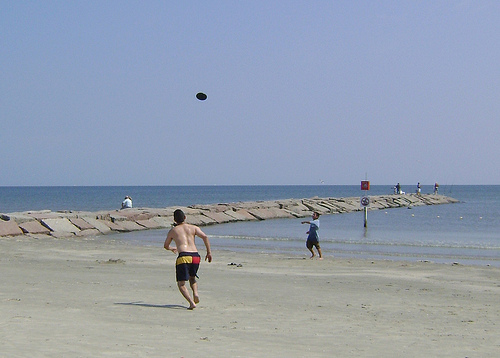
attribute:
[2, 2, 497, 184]
sky — clear, blue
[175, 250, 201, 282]
shorts — black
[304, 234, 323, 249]
shorts — blue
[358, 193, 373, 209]
sign — black, white, red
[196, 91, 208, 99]
frisbee — black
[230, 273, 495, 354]
sand — grey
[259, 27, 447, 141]
sky — clear, cloudless, blue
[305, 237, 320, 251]
pants — black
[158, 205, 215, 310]
person — yellow, red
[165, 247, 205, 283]
shorts — black